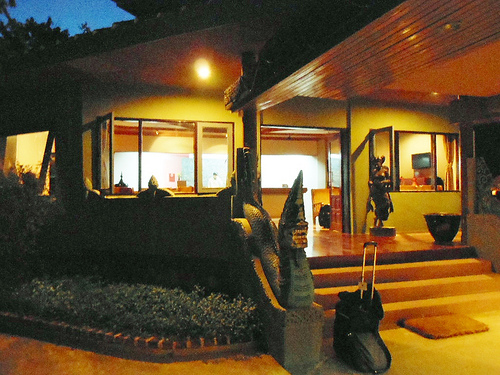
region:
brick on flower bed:
[213, 334, 227, 345]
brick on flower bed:
[203, 333, 215, 345]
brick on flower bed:
[189, 336, 201, 348]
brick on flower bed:
[161, 337, 173, 350]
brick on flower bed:
[146, 337, 159, 348]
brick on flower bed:
[136, 333, 148, 347]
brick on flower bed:
[123, 333, 134, 348]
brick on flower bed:
[88, 327, 97, 338]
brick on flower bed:
[250, 330, 258, 341]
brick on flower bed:
[238, 332, 250, 343]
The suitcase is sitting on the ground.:
[333, 219, 400, 371]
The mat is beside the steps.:
[401, 293, 489, 351]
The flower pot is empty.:
[413, 198, 465, 254]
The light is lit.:
[182, 42, 219, 90]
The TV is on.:
[408, 142, 434, 178]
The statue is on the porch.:
[354, 143, 402, 247]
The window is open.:
[86, 97, 140, 200]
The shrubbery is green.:
[19, 248, 261, 356]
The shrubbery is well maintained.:
[13, 263, 254, 338]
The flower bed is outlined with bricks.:
[1, 313, 256, 356]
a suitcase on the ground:
[336, 240, 390, 365]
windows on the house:
[109, 118, 233, 184]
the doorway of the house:
[264, 129, 344, 225]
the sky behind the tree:
[6, 18, 135, 30]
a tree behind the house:
[1, 16, 143, 56]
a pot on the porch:
[423, 203, 463, 240]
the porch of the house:
[285, 218, 490, 255]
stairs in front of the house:
[298, 256, 494, 322]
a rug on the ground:
[408, 308, 498, 335]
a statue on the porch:
[371, 156, 395, 230]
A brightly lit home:
[0, 0, 499, 374]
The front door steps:
[308, 258, 498, 327]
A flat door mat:
[401, 309, 487, 339]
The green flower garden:
[0, 164, 264, 356]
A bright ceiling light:
[194, 55, 214, 80]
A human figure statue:
[365, 150, 399, 237]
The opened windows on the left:
[95, 118, 245, 197]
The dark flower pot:
[422, 205, 464, 245]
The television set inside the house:
[409, 149, 435, 177]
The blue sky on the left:
[2, 0, 135, 39]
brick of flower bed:
[251, 326, 261, 342]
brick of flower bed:
[241, 331, 251, 340]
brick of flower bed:
[228, 333, 238, 345]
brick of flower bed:
[216, 334, 229, 344]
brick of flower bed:
[204, 335, 215, 346]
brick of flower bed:
[190, 335, 202, 348]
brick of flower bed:
[173, 339, 188, 350]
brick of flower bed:
[161, 337, 173, 349]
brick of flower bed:
[147, 338, 161, 348]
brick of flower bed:
[134, 335, 150, 345]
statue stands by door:
[362, 153, 402, 238]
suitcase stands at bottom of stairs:
[334, 239, 392, 373]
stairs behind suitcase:
[298, 246, 499, 328]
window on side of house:
[97, 117, 234, 194]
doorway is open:
[250, 122, 346, 237]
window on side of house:
[369, 129, 461, 196]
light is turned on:
[193, 55, 210, 81]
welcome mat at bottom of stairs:
[401, 312, 488, 339]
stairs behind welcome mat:
[299, 243, 499, 328]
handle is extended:
[359, 240, 379, 298]